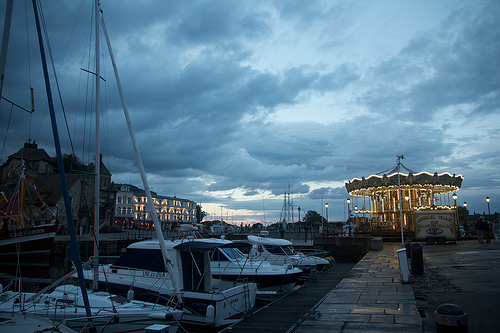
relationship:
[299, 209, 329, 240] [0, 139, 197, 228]
tree above buildings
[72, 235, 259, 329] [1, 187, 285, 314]
boat in harbor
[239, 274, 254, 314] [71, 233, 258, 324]
ladder on boat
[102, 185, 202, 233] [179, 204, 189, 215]
building with light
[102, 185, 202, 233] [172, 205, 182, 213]
building with light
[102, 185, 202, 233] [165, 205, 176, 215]
building with light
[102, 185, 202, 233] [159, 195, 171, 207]
building with light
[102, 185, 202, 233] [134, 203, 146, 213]
building with light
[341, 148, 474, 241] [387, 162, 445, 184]
building with lights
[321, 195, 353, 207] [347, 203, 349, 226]
lights on pole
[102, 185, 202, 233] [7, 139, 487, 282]
building along shore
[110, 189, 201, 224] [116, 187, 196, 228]
lights in building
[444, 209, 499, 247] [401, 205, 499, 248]
people in distance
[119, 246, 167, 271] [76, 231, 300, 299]
window on boat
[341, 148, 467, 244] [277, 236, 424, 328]
building on pier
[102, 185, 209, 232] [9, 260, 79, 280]
building on water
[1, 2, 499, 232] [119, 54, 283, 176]
sky of clouds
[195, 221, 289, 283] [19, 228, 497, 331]
boat at pier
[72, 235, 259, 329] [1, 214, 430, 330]
boat at pier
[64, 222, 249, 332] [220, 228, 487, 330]
boat at pier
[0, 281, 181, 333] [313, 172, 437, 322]
boat at pier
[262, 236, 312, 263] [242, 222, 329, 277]
window on boat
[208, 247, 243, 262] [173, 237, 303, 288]
window on boat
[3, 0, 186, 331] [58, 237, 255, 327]
mast on boat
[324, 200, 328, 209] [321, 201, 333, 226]
light on pole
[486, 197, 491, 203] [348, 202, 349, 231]
light on pole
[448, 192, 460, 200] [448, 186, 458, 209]
light on pole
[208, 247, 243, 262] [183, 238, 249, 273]
window on cabin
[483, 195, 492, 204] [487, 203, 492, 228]
light on lit post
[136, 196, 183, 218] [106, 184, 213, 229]
lights on building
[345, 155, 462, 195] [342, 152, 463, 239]
roof on carousel